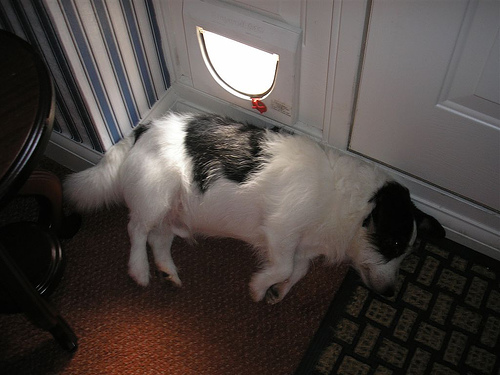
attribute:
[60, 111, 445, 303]
dog — white, black, hairy, resting, waiting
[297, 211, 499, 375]
door mat — patterned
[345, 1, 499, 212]
door — white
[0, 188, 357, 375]
carpet — dark brown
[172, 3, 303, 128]
pet door — locked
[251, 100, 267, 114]
lock — red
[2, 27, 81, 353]
table — wooden